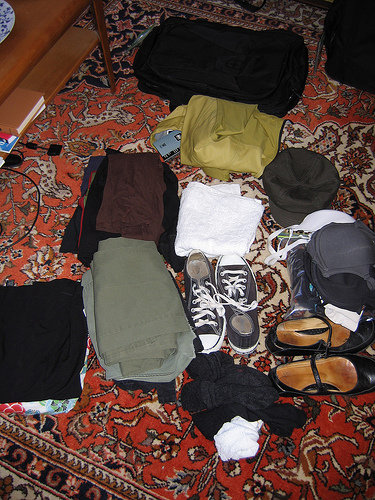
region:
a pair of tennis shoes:
[185, 250, 262, 345]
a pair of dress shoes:
[264, 312, 374, 402]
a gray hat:
[259, 145, 345, 218]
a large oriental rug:
[15, 27, 311, 487]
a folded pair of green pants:
[100, 269, 177, 385]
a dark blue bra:
[306, 230, 371, 286]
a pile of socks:
[183, 360, 269, 461]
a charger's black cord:
[8, 140, 59, 240]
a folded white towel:
[166, 182, 252, 252]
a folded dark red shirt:
[106, 159, 160, 233]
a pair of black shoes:
[268, 291, 374, 434]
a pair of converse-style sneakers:
[169, 239, 275, 379]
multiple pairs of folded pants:
[79, 239, 198, 408]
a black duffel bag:
[121, 14, 331, 123]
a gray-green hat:
[252, 136, 355, 237]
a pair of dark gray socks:
[173, 348, 280, 417]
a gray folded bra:
[291, 220, 373, 293]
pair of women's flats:
[245, 301, 369, 425]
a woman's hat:
[246, 139, 354, 247]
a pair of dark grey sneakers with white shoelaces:
[185, 256, 254, 346]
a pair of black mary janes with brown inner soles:
[271, 313, 373, 400]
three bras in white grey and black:
[281, 220, 373, 304]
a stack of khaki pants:
[90, 249, 184, 384]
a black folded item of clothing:
[3, 287, 78, 397]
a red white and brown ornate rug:
[75, 397, 188, 489]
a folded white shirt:
[178, 182, 258, 258]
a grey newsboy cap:
[274, 155, 326, 215]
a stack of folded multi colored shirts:
[81, 151, 175, 243]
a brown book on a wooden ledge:
[4, 86, 45, 127]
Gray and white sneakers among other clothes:
[182, 248, 260, 351]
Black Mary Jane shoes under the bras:
[265, 317, 373, 397]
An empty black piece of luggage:
[132, 15, 302, 113]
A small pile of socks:
[182, 351, 302, 461]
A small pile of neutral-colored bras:
[268, 209, 374, 322]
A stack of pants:
[82, 237, 191, 398]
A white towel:
[177, 181, 258, 256]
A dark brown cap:
[263, 146, 338, 226]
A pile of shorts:
[70, 150, 182, 271]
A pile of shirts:
[0, 280, 92, 415]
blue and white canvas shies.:
[177, 245, 267, 358]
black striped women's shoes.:
[267, 312, 374, 399]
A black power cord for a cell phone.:
[0, 136, 65, 221]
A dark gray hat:
[259, 148, 343, 229]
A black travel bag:
[128, 14, 312, 118]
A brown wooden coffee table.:
[0, 0, 114, 130]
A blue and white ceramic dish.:
[0, 0, 16, 38]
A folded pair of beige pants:
[79, 235, 188, 380]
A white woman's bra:
[264, 206, 354, 267]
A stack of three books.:
[1, 86, 49, 153]